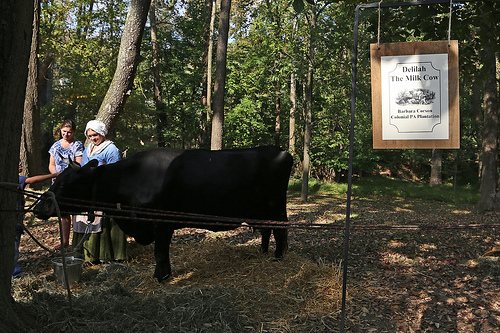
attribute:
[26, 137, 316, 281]
cow — large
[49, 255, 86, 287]
pail — metal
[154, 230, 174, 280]
leg — black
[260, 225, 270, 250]
leg — black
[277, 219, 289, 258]
leg — black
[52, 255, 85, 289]
metal bucket — shiny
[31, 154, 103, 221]
head — black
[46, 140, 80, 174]
shirt — blue, white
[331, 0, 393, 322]
pole — metal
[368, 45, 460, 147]
sign — wooden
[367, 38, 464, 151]
sign — wooden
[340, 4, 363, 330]
pole — metal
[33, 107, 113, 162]
women — standing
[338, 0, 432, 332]
bar — metal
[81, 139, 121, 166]
shirt — blue